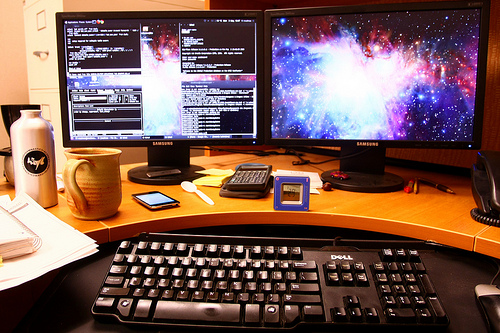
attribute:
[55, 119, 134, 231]
mug — coffee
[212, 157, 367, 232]
calculator — black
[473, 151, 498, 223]
phone — black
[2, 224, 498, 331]
shelf — smaller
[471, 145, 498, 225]
phone — black cord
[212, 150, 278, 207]
calculator — black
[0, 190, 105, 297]
papers — white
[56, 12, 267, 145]
monitor — samsung, black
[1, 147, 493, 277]
desk — dark brown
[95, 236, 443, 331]
keyboard — dell computer, black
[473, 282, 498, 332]
mouse — computer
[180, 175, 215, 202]
spoon — white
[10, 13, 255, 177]
monitor — computer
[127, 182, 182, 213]
phone — touch screen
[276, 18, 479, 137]
picture — background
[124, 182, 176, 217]
phone — cell